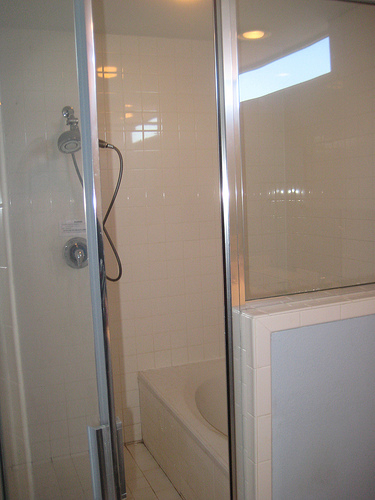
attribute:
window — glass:
[218, 33, 353, 91]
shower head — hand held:
[57, 129, 125, 280]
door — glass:
[6, 0, 128, 492]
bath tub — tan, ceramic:
[130, 362, 254, 471]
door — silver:
[89, 0, 235, 500]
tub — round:
[75, 317, 298, 469]